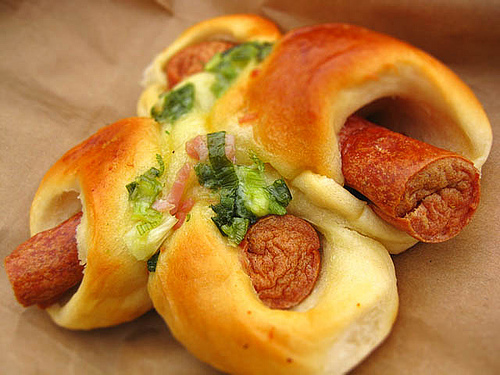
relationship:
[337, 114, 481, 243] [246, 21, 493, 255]
hot dog sticking out sections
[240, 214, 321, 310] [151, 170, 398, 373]
hotdog sticking out sections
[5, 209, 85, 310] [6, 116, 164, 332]
hotdog sticking out sections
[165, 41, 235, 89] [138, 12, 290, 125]
hotdog sticking out sections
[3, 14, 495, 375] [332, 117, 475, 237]
appetizer encasing hot dog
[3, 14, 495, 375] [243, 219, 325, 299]
appetizer encasing hot dog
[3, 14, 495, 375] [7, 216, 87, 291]
appetizer encasing hot dog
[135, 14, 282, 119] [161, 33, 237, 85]
croissant around hot dogs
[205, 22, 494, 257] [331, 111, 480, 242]
croissant around hot dogs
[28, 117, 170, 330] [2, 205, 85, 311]
croissant around hot dogs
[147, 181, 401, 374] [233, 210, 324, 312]
croissant around hot dogs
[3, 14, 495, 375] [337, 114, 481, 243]
appetizer with hot dog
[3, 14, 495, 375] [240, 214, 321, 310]
appetizer with hotdog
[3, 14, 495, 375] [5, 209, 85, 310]
appetizer with hotdog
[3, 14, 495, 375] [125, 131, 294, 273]
appetizer with garnish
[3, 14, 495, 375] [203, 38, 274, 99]
appetizer with garnish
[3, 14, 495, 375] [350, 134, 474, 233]
appetizer surrounds meat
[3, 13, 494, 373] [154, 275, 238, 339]
appetizer with bread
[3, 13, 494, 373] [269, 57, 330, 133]
appetizer with bread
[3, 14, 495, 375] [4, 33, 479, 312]
appetizer with hot dogs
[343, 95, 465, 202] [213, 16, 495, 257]
hole in bread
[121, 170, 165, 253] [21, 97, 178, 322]
hole in bread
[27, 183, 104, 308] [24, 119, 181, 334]
hole in bread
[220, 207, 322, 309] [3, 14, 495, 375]
hole in appetizer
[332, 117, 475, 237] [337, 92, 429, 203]
hot dog in hole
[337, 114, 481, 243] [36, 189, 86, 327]
hot dog in a hole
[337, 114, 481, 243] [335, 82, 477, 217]
hot dog in a hole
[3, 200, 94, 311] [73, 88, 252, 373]
hotdog in a buns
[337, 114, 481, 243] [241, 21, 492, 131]
hot dog in a buns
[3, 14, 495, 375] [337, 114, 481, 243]
appetizer inside hot dog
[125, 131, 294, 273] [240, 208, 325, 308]
garnish in hotdog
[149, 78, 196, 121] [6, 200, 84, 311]
garnish in hotdog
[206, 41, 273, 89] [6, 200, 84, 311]
garnish in hotdog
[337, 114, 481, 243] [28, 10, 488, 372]
hot dog hanging out of bun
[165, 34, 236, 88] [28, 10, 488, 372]
hotdog hanging out of bun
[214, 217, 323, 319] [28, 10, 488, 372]
hotdog hanging out of bun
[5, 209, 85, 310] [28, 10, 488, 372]
hotdog hanging out of bun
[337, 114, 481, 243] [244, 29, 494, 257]
hot dog in bun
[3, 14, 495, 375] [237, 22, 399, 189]
appetizer with bread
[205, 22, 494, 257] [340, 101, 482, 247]
croissant with meat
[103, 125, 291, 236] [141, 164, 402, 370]
garnish on bread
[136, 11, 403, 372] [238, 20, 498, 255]
croissant in middle croissant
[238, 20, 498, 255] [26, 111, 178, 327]
croissant in middle croissant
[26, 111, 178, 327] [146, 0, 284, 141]
croissant in middle croissant